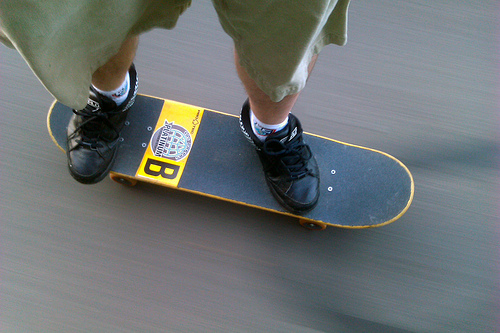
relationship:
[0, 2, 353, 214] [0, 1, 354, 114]
man wearing shorts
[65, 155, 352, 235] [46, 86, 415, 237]
edge of skateboard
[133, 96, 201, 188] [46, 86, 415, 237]
stripe on a skateboard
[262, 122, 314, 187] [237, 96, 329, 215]
shoe lace on a tennis shoe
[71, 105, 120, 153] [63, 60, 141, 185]
shoe lace on a tennis shoe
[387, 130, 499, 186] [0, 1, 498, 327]
shadow on ground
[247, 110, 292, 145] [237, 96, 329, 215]
ankle sock under tennis shoe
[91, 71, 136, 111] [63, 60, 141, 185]
ankle sock under tennis shoe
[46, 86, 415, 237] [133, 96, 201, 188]
skateboard has stripe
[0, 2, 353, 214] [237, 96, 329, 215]
man wearing tennis shoe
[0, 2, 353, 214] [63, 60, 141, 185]
man wearing tennis shoe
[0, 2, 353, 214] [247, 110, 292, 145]
man wearing ankle sock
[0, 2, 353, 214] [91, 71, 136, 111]
man wearing ankle sock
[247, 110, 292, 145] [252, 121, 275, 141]
ankle sock has design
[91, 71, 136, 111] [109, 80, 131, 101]
ankle sock has design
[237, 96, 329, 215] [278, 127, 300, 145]
tennis shoe has lettering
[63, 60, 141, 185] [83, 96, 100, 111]
tennis shoe has lettering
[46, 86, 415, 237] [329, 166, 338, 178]
skateboard has grommet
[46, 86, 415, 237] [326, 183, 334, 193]
skateboard has grommet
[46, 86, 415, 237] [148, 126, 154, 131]
skateboard has grommet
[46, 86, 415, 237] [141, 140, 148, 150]
skateboard has grommet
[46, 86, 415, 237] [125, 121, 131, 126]
skateboard has grommet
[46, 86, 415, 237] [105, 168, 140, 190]
skateboard has wheel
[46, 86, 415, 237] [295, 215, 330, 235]
skateboard has wheel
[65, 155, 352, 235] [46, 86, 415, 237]
edge of a skateboard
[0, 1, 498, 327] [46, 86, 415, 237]
ground under skateboard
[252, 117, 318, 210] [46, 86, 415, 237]
foot standing on skateboard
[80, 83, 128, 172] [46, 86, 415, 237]
foot standing on skateboard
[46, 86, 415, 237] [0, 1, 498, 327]
skateboard on ground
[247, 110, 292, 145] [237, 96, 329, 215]
ankle sock in tennis shoe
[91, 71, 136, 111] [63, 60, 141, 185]
ankle sock in tennis shoe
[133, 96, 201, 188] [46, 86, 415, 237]
stripe on skateboard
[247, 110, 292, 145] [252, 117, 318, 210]
ankle sock on foot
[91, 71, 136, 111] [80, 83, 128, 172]
ankle sock on foot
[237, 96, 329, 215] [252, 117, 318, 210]
tennis shoe on foot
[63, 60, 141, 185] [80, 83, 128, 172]
tennis shoe on foot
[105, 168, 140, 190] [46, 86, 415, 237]
wheel under skateboard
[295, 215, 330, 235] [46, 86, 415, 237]
wheel under skateboard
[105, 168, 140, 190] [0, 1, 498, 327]
wheel on ground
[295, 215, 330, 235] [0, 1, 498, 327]
wheel on ground